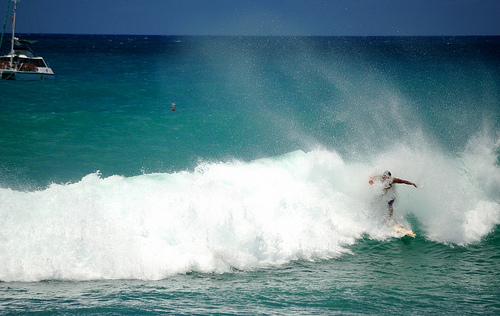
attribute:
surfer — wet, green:
[346, 148, 423, 248]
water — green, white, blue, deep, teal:
[280, 266, 376, 312]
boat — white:
[0, 19, 76, 91]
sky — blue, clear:
[272, 12, 330, 33]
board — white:
[390, 222, 415, 246]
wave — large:
[222, 156, 285, 248]